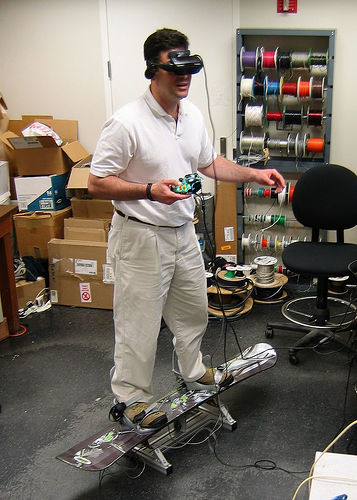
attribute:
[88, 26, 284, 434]
man — playing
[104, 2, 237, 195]
door — white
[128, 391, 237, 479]
frame — metal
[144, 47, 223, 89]
goggles — video game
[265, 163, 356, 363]
chair — black, desk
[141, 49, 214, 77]
goggles — virtual reality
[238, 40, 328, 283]
rolls — many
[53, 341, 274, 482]
snowboarding game — virtual reality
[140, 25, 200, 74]
hair — long, dark, thick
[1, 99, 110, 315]
boxes — cardboard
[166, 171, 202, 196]
game controller — video game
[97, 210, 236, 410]
pair — business casual, khaki, slacks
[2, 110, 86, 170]
box — many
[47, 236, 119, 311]
box — various sized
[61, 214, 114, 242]
box — various sized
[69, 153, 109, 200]
box — various sized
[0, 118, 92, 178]
box — various sized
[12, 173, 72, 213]
box — various sized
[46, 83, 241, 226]
shirt — short, white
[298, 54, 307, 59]
wire — gray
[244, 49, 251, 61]
wire — purple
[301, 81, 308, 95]
wire — orange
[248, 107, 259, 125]
wire — white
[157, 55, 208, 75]
glasses — VR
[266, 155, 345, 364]
chair — black